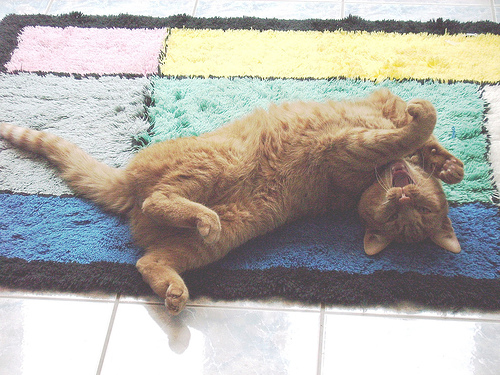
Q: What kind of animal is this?
A: A cat.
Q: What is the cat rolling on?
A: A throw rug.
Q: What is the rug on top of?
A: Tiled flooring.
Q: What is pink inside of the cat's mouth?
A: The tongue.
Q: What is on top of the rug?
A: A tan cat.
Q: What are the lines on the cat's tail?
A: Orange stripes.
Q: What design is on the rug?
A: Colorful squares.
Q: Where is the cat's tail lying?
A: On a gray square.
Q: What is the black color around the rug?
A: The trim.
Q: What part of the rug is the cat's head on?
A: A blue square.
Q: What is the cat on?
A: Rug.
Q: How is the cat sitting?
A: Body twisted.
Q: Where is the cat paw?
A: In the air.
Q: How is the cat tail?
A: Stripes on it.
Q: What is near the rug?
A: Tile.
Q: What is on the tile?
A: Cat paw.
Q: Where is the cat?
A: On the ground.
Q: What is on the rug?
A: Cat head.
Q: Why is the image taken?
A: Remembrance.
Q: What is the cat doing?
A: Lying on back.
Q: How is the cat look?
A: Mouth open.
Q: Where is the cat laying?
A: On rug.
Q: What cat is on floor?
A: Tabby cat.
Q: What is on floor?
A: Bath mat.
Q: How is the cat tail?
A: White and orange.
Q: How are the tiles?
A: Ceramic.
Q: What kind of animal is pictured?
A: A cat.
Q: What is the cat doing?
A: Rolling around on its back.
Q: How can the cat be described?
A: A striped orange cat.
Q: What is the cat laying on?
A: A multi-colored rug.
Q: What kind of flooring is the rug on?
A: White tile.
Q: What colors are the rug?
A: Blue, green, yellow, pink, black and teal.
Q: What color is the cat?
A: Orange.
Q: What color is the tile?
A: White.